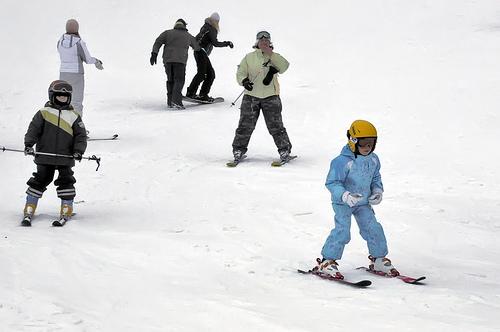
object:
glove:
[366, 188, 382, 206]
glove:
[241, 77, 254, 92]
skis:
[296, 268, 372, 287]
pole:
[0, 146, 101, 172]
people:
[149, 18, 203, 109]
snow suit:
[24, 101, 89, 201]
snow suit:
[321, 143, 388, 259]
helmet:
[346, 120, 377, 153]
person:
[186, 12, 234, 101]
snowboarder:
[180, 12, 234, 104]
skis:
[51, 212, 77, 226]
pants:
[320, 202, 389, 260]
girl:
[57, 18, 105, 117]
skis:
[356, 266, 427, 283]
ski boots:
[313, 256, 345, 279]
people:
[231, 31, 293, 161]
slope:
[3, 2, 494, 327]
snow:
[1, 1, 499, 330]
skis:
[20, 214, 34, 226]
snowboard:
[180, 94, 225, 104]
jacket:
[235, 48, 291, 99]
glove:
[340, 190, 362, 208]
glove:
[260, 65, 279, 85]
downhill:
[3, 0, 498, 326]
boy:
[23, 79, 88, 219]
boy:
[315, 120, 400, 279]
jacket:
[57, 33, 99, 74]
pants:
[232, 93, 293, 153]